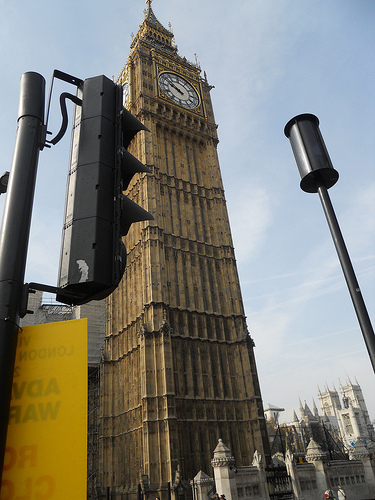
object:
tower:
[98, 0, 272, 500]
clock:
[157, 70, 201, 110]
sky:
[2, 0, 375, 401]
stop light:
[56, 74, 155, 306]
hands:
[165, 77, 184, 95]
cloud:
[234, 161, 375, 251]